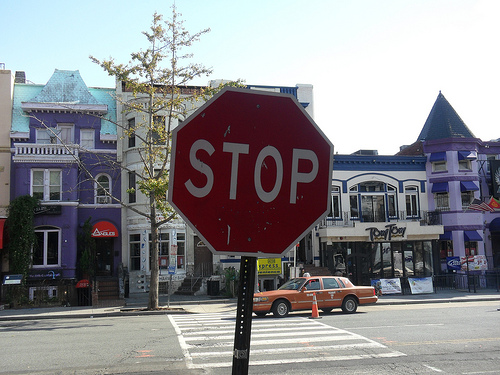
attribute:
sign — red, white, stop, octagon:
[167, 88, 336, 260]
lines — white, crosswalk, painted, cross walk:
[165, 301, 446, 374]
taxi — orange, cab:
[251, 274, 380, 321]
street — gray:
[0, 300, 499, 375]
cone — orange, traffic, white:
[310, 291, 322, 320]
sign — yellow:
[253, 257, 283, 278]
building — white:
[321, 150, 442, 297]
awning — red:
[86, 220, 118, 238]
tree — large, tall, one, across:
[21, 3, 249, 308]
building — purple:
[415, 82, 492, 290]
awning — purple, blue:
[430, 152, 446, 164]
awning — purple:
[461, 150, 477, 161]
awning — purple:
[467, 229, 478, 244]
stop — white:
[184, 136, 322, 208]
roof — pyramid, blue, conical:
[409, 88, 480, 148]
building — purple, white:
[15, 70, 123, 307]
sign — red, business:
[458, 255, 474, 266]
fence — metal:
[165, 261, 209, 297]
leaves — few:
[93, 11, 257, 219]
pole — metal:
[232, 257, 256, 374]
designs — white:
[93, 229, 117, 237]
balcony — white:
[9, 140, 80, 164]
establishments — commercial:
[2, 65, 498, 311]